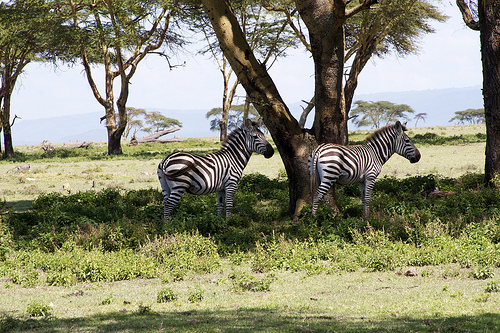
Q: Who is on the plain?
A: Zebras.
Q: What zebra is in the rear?
A: The second one.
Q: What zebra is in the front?
A: The one leading the other.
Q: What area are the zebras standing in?
A: The shade.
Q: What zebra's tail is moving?
A: The rear zebra.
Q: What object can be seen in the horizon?
A: Mountains.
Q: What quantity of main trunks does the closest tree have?
A: Two.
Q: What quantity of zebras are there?
A: Two.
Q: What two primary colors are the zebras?
A: White and black.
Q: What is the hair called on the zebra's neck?
A: Maim.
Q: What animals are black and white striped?
A: Zebras.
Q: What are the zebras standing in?
A: The shad.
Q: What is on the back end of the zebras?
A: The tail.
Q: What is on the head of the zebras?
A: The ears.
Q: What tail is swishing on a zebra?
A: The left one.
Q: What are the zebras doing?
A: Relaxing.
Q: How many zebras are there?
A: Two.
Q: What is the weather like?
A: Sunny.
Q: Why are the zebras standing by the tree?
A: It is shady there.